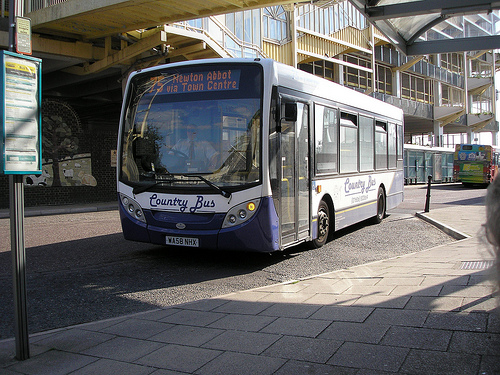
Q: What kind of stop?
A: A bus stop.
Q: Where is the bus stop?
A: On the street.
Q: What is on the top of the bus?
A: A sign.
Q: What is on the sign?
A: The bus destination.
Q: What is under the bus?
A: The pavement.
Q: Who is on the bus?
A: Passengers.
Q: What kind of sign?
A: A bus stop sign.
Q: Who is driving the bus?
A: A bus operator.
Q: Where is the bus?
A: Bus stop.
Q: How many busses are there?
A: Two.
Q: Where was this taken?
A: At a bus stop.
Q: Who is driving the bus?
A: The bus driver.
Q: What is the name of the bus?
A: Country Bus.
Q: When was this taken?
A: During the day.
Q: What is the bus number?
A: 75.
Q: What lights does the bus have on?
A: The turning signal.